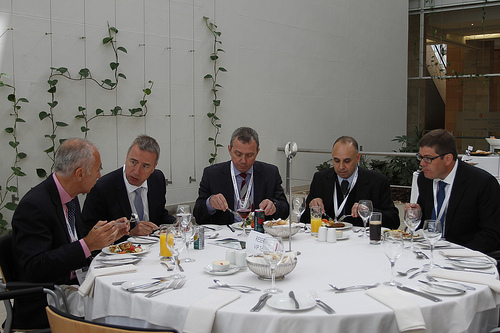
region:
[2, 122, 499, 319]
five men sitting at a table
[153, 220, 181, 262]
a glass of orange juice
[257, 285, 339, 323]
a plate with no food on it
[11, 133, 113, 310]
a man wearing a pink shirt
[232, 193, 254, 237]
a glass of red wine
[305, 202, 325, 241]
a glass of orange juice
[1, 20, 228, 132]
ivy growing on a wall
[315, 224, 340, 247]
salt and pepper shakers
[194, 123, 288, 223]
a man with a striped tie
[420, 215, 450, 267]
an empty wine glass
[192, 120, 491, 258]
Men sitting at table eating.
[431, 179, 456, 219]
Man wearing blue tie around neck.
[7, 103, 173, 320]
Men dressed in black suits.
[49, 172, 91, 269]
Man's pink cuff and collar showing under black suit.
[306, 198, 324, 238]
Glass of orange juice sitting on table.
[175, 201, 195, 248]
Glass of water sitting on table.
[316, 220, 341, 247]
Salt and pepper shaker sitting on table.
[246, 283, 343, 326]
White plate with cutlery sitting on table.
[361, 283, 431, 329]
Folded white napkin lying on table.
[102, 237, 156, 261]
Plate of food sitting in front of man at table.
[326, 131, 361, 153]
Man has dark hair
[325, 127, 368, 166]
Man has receding hair.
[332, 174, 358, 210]
Man wearing dark tie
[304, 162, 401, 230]
Man wearing black jacket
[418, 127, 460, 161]
Man has dark hair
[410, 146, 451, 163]
Man wearing corrective lenses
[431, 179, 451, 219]
Man wearing dark blue tie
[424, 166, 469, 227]
Man wearing white shirt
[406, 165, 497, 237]
Man wearing black jacket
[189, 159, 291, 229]
Man wearing black jacket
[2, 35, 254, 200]
green vines growing up the back wall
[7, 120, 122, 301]
man with short gray hair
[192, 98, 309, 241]
man with short brown hair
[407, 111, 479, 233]
man wearing black rim glasses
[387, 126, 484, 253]
man wearing blue tie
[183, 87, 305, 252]
man wearing gray and burgandy tie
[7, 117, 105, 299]
man wearing pink tie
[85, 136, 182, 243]
man wearing white dress shirt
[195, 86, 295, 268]
man wearing white medal around his neck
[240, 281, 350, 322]
white plate and silver flatware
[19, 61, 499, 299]
a group of men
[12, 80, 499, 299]
a group of men eating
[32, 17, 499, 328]
a group of men at table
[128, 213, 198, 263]
a glass of orange juice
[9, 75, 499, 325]
men wearing suits and ties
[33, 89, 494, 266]
group of men sitting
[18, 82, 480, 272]
men eating at table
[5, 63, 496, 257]
group of men talking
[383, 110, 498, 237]
a man wearing glasses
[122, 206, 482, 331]
a circle table with white table cloth